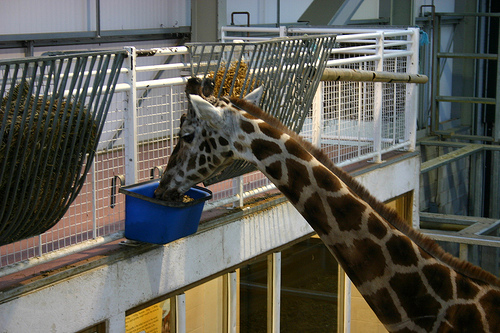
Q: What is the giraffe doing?
A: Drinking water.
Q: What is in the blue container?
A: Water.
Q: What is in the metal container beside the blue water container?
A: Hay.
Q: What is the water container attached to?
A: A white metal fence.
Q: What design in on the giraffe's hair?
A: White with brown spots.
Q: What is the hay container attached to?
A: A white metal fence.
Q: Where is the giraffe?
A: In front of the white metal fence.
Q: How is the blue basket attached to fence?
A: Two hooks.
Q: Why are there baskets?
A: To hold food.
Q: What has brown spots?
A: Giraffe.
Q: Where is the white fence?
A: Along the balcony.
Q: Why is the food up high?
A: Giraffe has long neck.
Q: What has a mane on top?
A: Giraffe neck.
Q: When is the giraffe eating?
A: Now.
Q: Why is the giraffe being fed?
A: It's in captivity.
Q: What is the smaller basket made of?
A: Plastic.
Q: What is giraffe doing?
A: Eating.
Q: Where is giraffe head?
A: In bucket.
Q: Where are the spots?
A: On giraffe.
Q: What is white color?
A: Fence.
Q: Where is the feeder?
A: On fence.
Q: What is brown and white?
A: Giraffe.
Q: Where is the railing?
A: Stair.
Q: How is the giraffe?
A: Spotted.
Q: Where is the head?
A: On giraffe.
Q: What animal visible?
A: Giraffe.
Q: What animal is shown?
A: Giraffe.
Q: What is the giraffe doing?
A: Eating.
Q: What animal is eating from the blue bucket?
A: A giraffe.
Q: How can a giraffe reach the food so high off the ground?
A: His long neck.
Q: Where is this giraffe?
A: At a zoo.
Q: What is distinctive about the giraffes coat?
A: Its large spots.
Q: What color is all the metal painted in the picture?
A: White.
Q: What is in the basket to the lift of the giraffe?
A: Hay.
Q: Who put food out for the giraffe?
A: A zoo keeper.